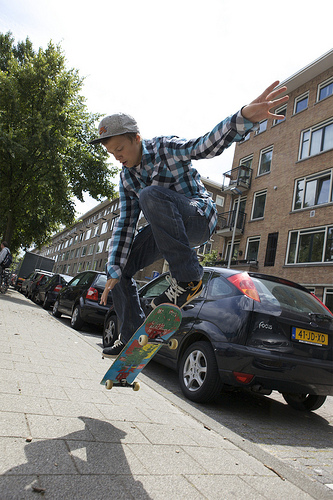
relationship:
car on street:
[129, 254, 331, 414] [5, 254, 329, 484]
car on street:
[55, 269, 158, 344] [5, 254, 329, 484]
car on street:
[34, 274, 76, 314] [5, 254, 329, 484]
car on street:
[18, 269, 54, 296] [5, 254, 329, 484]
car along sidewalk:
[129, 254, 331, 414] [0, 290, 315, 498]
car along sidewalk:
[55, 269, 158, 344] [0, 290, 315, 498]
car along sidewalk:
[34, 274, 76, 314] [0, 290, 315, 498]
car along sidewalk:
[18, 269, 54, 296] [0, 290, 315, 498]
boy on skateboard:
[94, 77, 298, 362] [98, 298, 184, 393]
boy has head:
[94, 77, 298, 362] [96, 116, 143, 171]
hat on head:
[92, 112, 135, 144] [96, 116, 143, 171]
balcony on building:
[225, 165, 248, 193] [225, 52, 330, 407]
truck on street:
[13, 245, 59, 300] [5, 254, 329, 484]